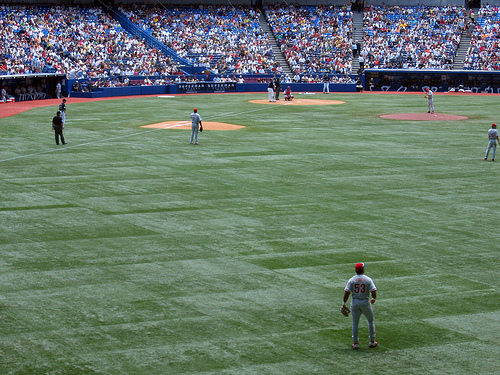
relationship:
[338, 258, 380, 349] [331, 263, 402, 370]
man in uniform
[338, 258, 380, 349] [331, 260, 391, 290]
man wearing hat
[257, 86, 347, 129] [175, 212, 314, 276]
plate on field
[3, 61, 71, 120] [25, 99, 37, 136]
one teams dug out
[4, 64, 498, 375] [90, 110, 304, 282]
inside a baseball stadium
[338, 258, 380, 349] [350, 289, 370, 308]
man number 53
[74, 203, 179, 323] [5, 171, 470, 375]
patch of baseball field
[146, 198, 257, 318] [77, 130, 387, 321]
patch of green baseball field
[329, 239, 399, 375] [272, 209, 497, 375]
baseball player on field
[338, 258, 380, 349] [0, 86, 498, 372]
man stands on field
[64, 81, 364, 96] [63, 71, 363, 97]
wall in front of stands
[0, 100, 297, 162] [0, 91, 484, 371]
line painted on grass